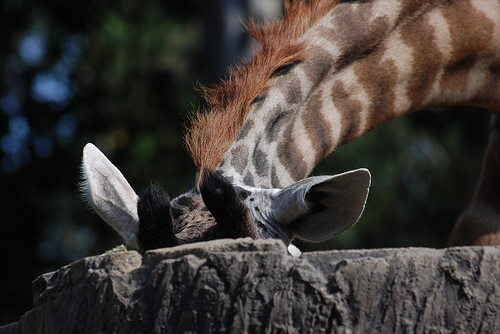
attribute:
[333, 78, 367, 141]
spot — brown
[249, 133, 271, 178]
spot — brown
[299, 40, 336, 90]
spot — brown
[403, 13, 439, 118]
spot — brown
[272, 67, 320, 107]
spot — brown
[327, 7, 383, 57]
spot — brown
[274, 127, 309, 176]
spot — brown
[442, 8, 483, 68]
spot — brown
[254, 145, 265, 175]
spot — brown